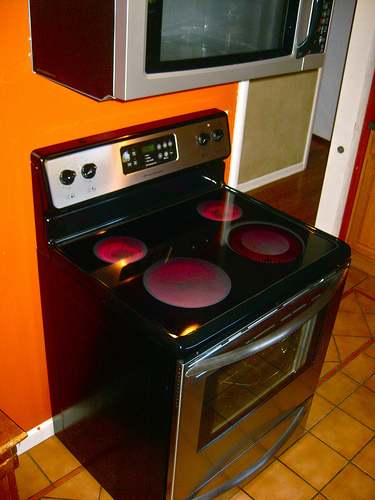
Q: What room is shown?
A: It is a kitchen.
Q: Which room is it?
A: It is a kitchen.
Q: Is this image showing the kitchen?
A: Yes, it is showing the kitchen.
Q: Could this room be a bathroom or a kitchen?
A: It is a kitchen.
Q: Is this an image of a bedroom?
A: No, the picture is showing a kitchen.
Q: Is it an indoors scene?
A: Yes, it is indoors.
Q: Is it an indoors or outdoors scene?
A: It is indoors.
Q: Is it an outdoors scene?
A: No, it is indoors.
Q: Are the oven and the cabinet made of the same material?
A: No, the oven is made of glass and the cabinet is made of wood.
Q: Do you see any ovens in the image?
A: Yes, there is an oven.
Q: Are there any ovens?
A: Yes, there is an oven.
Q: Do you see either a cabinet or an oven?
A: Yes, there is an oven.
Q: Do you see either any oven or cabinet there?
A: Yes, there is an oven.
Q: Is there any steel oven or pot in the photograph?
A: Yes, there is a steel oven.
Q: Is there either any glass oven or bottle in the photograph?
A: Yes, there is a glass oven.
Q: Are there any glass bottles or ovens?
A: Yes, there is a glass oven.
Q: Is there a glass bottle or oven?
A: Yes, there is a glass oven.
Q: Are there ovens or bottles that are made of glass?
A: Yes, the oven is made of glass.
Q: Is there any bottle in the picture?
A: No, there are no bottles.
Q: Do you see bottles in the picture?
A: No, there are no bottles.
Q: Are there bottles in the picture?
A: No, there are no bottles.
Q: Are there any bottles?
A: No, there are no bottles.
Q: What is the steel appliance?
A: The appliance is an oven.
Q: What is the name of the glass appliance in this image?
A: The appliance is an oven.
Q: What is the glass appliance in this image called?
A: The appliance is an oven.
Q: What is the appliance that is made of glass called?
A: The appliance is an oven.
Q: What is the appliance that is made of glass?
A: The appliance is an oven.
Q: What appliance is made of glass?
A: The appliance is an oven.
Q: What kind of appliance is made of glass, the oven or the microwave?
A: The oven is made of glass.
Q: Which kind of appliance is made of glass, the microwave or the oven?
A: The oven is made of glass.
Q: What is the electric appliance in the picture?
A: The appliance is an oven.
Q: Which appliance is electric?
A: The appliance is an oven.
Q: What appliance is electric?
A: The appliance is an oven.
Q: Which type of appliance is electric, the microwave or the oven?
A: The oven is electric.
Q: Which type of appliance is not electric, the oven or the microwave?
A: The microwave is not electric.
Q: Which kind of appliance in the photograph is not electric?
A: The appliance is a microwave.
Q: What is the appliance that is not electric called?
A: The appliance is a microwave.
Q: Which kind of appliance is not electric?
A: The appliance is a microwave.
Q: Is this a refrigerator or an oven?
A: This is an oven.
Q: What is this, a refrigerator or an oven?
A: This is an oven.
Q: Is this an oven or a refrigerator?
A: This is an oven.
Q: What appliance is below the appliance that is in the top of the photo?
A: The appliance is an oven.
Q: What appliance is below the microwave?
A: The appliance is an oven.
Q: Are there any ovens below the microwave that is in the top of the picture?
A: Yes, there is an oven below the microwave.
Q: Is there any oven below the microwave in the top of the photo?
A: Yes, there is an oven below the microwave.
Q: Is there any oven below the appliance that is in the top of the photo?
A: Yes, there is an oven below the microwave.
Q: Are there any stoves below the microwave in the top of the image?
A: No, there is an oven below the microwave.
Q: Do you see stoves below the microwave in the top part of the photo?
A: No, there is an oven below the microwave.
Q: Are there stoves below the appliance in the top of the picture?
A: No, there is an oven below the microwave.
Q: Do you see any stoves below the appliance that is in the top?
A: No, there is an oven below the microwave.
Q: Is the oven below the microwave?
A: Yes, the oven is below the microwave.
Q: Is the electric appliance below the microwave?
A: Yes, the oven is below the microwave.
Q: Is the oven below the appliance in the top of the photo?
A: Yes, the oven is below the microwave.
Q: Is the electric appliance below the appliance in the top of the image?
A: Yes, the oven is below the microwave.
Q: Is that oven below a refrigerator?
A: No, the oven is below the microwave.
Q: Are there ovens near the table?
A: Yes, there is an oven near the table.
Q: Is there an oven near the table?
A: Yes, there is an oven near the table.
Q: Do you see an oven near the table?
A: Yes, there is an oven near the table.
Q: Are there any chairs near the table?
A: No, there is an oven near the table.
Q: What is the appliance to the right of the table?
A: The appliance is an oven.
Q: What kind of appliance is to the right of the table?
A: The appliance is an oven.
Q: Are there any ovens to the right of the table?
A: Yes, there is an oven to the right of the table.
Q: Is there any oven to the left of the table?
A: No, the oven is to the right of the table.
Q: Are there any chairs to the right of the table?
A: No, there is an oven to the right of the table.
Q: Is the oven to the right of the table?
A: Yes, the oven is to the right of the table.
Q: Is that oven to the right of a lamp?
A: No, the oven is to the right of the table.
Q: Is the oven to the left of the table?
A: No, the oven is to the right of the table.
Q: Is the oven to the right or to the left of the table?
A: The oven is to the right of the table.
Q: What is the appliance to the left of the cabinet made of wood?
A: The appliance is an oven.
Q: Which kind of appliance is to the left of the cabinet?
A: The appliance is an oven.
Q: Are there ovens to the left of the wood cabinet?
A: Yes, there is an oven to the left of the cabinet.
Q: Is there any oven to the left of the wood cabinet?
A: Yes, there is an oven to the left of the cabinet.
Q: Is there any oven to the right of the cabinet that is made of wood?
A: No, the oven is to the left of the cabinet.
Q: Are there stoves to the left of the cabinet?
A: No, there is an oven to the left of the cabinet.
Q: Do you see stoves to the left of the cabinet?
A: No, there is an oven to the left of the cabinet.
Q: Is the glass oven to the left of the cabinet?
A: Yes, the oven is to the left of the cabinet.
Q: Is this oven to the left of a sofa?
A: No, the oven is to the left of the cabinet.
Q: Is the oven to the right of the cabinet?
A: No, the oven is to the left of the cabinet.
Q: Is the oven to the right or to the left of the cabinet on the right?
A: The oven is to the left of the cabinet.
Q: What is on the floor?
A: The oven is on the floor.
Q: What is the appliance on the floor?
A: The appliance is an oven.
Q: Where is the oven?
A: The oven is on the floor.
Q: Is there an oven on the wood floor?
A: Yes, there is an oven on the floor.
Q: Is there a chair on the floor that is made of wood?
A: No, there is an oven on the floor.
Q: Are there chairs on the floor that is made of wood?
A: No, there is an oven on the floor.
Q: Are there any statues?
A: No, there are no statues.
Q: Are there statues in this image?
A: No, there are no statues.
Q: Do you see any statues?
A: No, there are no statues.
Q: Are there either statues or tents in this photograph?
A: No, there are no statues or tents.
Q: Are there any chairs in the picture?
A: No, there are no chairs.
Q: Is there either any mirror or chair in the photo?
A: No, there are no chairs or mirrors.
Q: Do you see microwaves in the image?
A: Yes, there is a microwave.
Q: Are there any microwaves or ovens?
A: Yes, there is a microwave.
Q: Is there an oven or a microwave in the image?
A: Yes, there is a microwave.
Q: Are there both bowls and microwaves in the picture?
A: No, there is a microwave but no bowls.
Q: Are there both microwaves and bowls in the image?
A: No, there is a microwave but no bowls.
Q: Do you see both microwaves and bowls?
A: No, there is a microwave but no bowls.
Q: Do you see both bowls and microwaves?
A: No, there is a microwave but no bowls.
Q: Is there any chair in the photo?
A: No, there are no chairs.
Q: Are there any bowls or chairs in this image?
A: No, there are no chairs or bowls.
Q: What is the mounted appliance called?
A: The appliance is a microwave.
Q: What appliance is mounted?
A: The appliance is a microwave.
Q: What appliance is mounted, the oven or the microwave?
A: The microwave is mounted.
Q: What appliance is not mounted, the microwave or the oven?
A: The oven is not mounted.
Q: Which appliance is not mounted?
A: The appliance is an oven.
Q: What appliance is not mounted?
A: The appliance is an oven.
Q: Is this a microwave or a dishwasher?
A: This is a microwave.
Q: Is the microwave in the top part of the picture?
A: Yes, the microwave is in the top of the image.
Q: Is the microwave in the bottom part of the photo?
A: No, the microwave is in the top of the image.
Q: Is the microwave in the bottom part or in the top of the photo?
A: The microwave is in the top of the image.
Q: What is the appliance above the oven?
A: The appliance is a microwave.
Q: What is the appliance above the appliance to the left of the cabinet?
A: The appliance is a microwave.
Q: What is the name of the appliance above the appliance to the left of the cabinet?
A: The appliance is a microwave.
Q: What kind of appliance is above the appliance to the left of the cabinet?
A: The appliance is a microwave.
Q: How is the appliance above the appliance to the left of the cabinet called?
A: The appliance is a microwave.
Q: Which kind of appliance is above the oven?
A: The appliance is a microwave.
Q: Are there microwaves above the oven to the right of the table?
A: Yes, there is a microwave above the oven.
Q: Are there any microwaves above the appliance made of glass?
A: Yes, there is a microwave above the oven.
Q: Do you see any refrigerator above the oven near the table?
A: No, there is a microwave above the oven.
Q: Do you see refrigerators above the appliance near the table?
A: No, there is a microwave above the oven.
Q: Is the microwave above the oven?
A: Yes, the microwave is above the oven.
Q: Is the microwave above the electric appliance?
A: Yes, the microwave is above the oven.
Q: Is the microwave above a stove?
A: No, the microwave is above the oven.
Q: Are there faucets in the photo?
A: No, there are no faucets.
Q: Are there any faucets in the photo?
A: No, there are no faucets.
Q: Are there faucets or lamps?
A: No, there are no faucets or lamps.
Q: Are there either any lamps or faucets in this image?
A: No, there are no faucets or lamps.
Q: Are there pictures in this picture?
A: No, there are no pictures.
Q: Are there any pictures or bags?
A: No, there are no pictures or bags.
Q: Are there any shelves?
A: No, there are no shelves.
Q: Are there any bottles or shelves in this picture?
A: No, there are no shelves or bottles.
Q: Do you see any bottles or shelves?
A: No, there are no shelves or bottles.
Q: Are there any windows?
A: Yes, there is a window.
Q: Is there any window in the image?
A: Yes, there is a window.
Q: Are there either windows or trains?
A: Yes, there is a window.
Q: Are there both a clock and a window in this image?
A: Yes, there are both a window and a clock.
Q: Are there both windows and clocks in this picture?
A: Yes, there are both a window and a clock.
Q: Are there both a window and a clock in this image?
A: Yes, there are both a window and a clock.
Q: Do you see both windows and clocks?
A: Yes, there are both a window and a clock.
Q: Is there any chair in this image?
A: No, there are no chairs.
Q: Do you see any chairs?
A: No, there are no chairs.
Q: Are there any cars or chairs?
A: No, there are no chairs or cars.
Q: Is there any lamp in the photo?
A: No, there are no lamps.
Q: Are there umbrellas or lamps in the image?
A: No, there are no lamps or umbrellas.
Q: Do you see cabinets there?
A: Yes, there is a cabinet.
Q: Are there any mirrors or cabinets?
A: Yes, there is a cabinet.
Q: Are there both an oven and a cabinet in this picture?
A: Yes, there are both a cabinet and an oven.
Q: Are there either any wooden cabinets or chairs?
A: Yes, there is a wood cabinet.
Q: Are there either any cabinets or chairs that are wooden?
A: Yes, the cabinet is wooden.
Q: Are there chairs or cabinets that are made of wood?
A: Yes, the cabinet is made of wood.